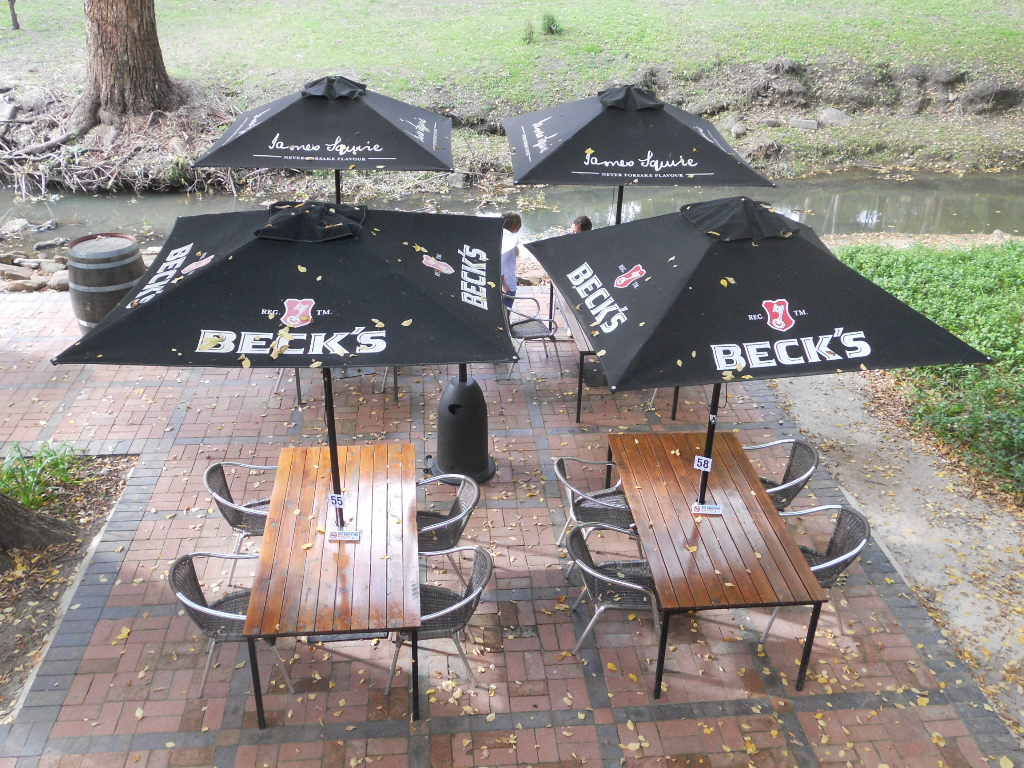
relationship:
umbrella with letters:
[48, 199, 511, 550] [192, 320, 394, 355]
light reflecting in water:
[774, 202, 885, 226] [2, 182, 990, 243]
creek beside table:
[9, 162, 1021, 245] [600, 430, 840, 699]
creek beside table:
[9, 162, 1021, 245] [238, 435, 422, 725]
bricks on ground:
[2, 351, 1012, 755] [0, 0, 1022, 765]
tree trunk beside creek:
[13, 0, 219, 167] [2, 167, 1022, 239]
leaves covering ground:
[0, 426, 42, 476] [19, 260, 1020, 768]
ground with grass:
[19, 260, 1020, 768] [773, 215, 1011, 458]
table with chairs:
[605, 430, 826, 700] [164, 460, 299, 700]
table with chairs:
[238, 435, 422, 725] [164, 460, 299, 700]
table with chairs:
[238, 435, 422, 725] [382, 473, 493, 707]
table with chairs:
[600, 430, 840, 699] [555, 455, 655, 654]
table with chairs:
[600, 430, 840, 699] [749, 434, 870, 657]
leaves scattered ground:
[705, 702, 960, 716] [16, 346, 991, 735]